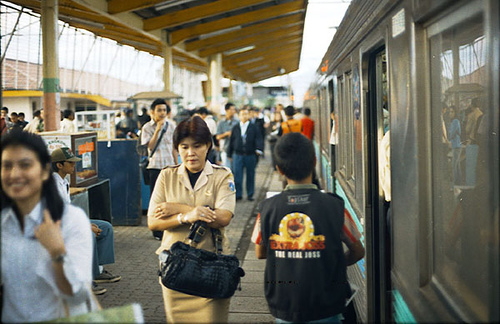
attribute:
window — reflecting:
[431, 28, 487, 298]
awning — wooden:
[11, 2, 300, 78]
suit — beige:
[148, 169, 235, 322]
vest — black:
[262, 203, 354, 315]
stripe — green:
[38, 78, 63, 98]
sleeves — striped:
[343, 211, 364, 246]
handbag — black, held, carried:
[173, 236, 245, 298]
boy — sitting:
[46, 141, 125, 292]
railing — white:
[75, 115, 129, 145]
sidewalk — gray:
[234, 217, 269, 317]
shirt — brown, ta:
[150, 169, 225, 253]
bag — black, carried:
[176, 249, 272, 291]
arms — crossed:
[150, 206, 244, 228]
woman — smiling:
[4, 129, 91, 316]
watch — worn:
[174, 212, 185, 223]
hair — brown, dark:
[177, 119, 215, 141]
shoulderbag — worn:
[142, 126, 173, 167]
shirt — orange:
[282, 124, 300, 133]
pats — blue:
[236, 153, 269, 206]